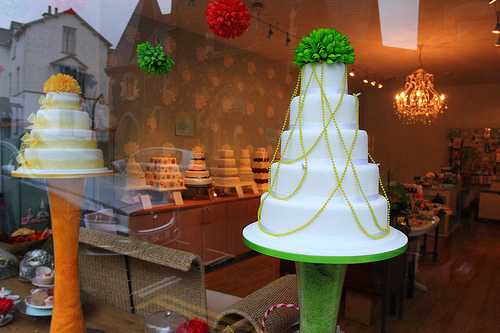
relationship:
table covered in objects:
[409, 218, 441, 293] [384, 174, 452, 226]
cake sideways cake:
[244, 21, 411, 246] [19, 73, 109, 178]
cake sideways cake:
[146, 150, 186, 196] [188, 140, 208, 199]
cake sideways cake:
[188, 140, 208, 199] [212, 146, 239, 187]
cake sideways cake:
[212, 146, 239, 187] [121, 153, 148, 196]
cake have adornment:
[16, 90, 102, 169] [40, 72, 82, 94]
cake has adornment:
[16, 90, 102, 169] [40, 72, 82, 94]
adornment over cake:
[40, 72, 82, 94] [16, 90, 102, 169]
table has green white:
[241, 221, 410, 331] [241, 220, 408, 331]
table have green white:
[241, 221, 410, 331] [241, 220, 408, 331]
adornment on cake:
[40, 72, 82, 94] [9, 70, 115, 179]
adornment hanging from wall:
[130, 41, 182, 73] [117, 19, 330, 242]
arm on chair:
[219, 278, 303, 328] [37, 202, 343, 331]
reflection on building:
[0, 0, 499, 330] [14, 14, 114, 256]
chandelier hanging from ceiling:
[392, 41, 450, 125] [353, 5, 484, 85]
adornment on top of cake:
[293, 26, 357, 63] [254, 64, 391, 245]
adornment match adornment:
[293, 26, 357, 63] [40, 72, 82, 94]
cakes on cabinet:
[145, 144, 188, 204] [114, 196, 283, 279]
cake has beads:
[254, 64, 391, 245] [313, 65, 338, 136]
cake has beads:
[16, 90, 102, 169] [331, 149, 363, 206]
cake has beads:
[212, 146, 239, 187] [353, 201, 391, 238]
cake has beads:
[188, 140, 208, 199] [286, 72, 306, 159]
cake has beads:
[146, 150, 186, 196] [263, 158, 308, 201]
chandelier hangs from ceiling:
[392, 41, 450, 125] [142, 0, 499, 87]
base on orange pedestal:
[43, 180, 103, 329] [43, 175, 85, 332]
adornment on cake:
[293, 26, 357, 63] [254, 64, 391, 245]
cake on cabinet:
[146, 150, 186, 196] [114, 196, 283, 279]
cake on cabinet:
[9, 70, 115, 179] [114, 196, 283, 279]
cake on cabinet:
[188, 140, 208, 199] [114, 196, 283, 279]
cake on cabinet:
[212, 146, 239, 187] [114, 196, 283, 279]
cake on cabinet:
[244, 21, 411, 246] [114, 196, 283, 279]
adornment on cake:
[40, 72, 82, 94] [16, 90, 102, 169]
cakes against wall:
[115, 144, 268, 204] [106, 1, 300, 173]